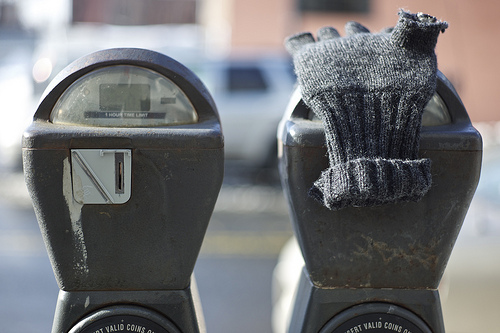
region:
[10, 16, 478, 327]
Two parking meters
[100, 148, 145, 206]
Coin slot for the meter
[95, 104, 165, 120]
1 hour time limit on the meter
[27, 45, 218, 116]
Top of the meter is rounded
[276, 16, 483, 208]
Glove on the top of the meter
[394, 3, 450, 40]
The glove is not enclosed on the thumb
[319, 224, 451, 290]
The meter is chipped and rusting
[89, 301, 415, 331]
The words "valid coins" are on both meters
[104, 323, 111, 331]
white letter on parking meter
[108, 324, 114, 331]
white letter on parking meter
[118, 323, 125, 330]
white letter on parking meter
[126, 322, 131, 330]
white letter on parking meter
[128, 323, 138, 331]
white letter on parking meter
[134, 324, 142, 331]
white letter on parking meter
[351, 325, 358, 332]
white letter on parking meter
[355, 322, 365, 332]
white letter on parking meter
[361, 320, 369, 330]
white letter on parking meter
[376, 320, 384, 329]
white letter on parking meter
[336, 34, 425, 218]
This is a dark grey glove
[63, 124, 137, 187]
This is a silver opening for the change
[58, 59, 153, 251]
This machine is a dark gray color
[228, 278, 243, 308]
There is a patch of black asphalt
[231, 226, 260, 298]
There are yellow lines here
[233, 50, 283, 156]
There is a SUV in the background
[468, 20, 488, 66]
There is a wall here that is terra cotta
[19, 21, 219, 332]
parking meter on the sidewalk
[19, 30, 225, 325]
parking meter on the sidewalk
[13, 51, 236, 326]
parking meter on the sidewalk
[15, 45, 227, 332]
parking meter on the sidewalk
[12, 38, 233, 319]
parking meter on the sidewalk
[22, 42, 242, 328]
parking meter on the sidewalk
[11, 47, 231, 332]
parking meter on the sidewalk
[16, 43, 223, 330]
parking meter on the sidewalk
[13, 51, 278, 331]
parking meter on the sidewalk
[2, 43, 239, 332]
parking meter on the sidewalk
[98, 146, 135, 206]
slot for the coin's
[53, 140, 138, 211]
plate for the slot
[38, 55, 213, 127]
window of the meter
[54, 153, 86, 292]
wearing on the meter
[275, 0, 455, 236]
glove on the meter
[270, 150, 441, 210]
cuff of the glove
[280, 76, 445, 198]
ribbing on the cuff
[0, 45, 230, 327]
parking meter on the street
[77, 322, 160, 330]
writing on the meter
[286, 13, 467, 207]
glove on the meter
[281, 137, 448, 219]
bottom of the glove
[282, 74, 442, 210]
black glove on meter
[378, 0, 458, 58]
hole in the thumb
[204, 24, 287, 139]
blurry car in distance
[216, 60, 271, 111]
window on the car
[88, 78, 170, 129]
words on the meter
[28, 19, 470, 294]
two meters side by side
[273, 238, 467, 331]
bottom part of meter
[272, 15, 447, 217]
glove on a meter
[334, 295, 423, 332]
dial on a meter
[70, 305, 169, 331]
dial on a meter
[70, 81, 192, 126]
dial on a meter